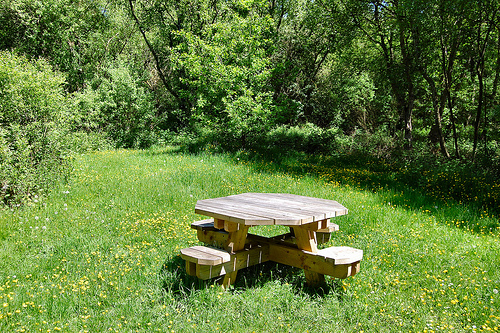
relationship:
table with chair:
[196, 191, 349, 246] [181, 244, 231, 262]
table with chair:
[196, 191, 349, 246] [303, 246, 365, 264]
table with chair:
[196, 191, 349, 246] [192, 219, 215, 230]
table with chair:
[196, 191, 349, 246] [320, 221, 337, 232]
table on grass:
[196, 191, 349, 246] [0, 142, 499, 333]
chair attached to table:
[303, 246, 365, 264] [196, 191, 349, 246]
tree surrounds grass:
[409, 0, 451, 158] [0, 142, 499, 333]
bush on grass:
[0, 46, 73, 217] [0, 142, 499, 333]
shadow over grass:
[160, 256, 222, 303] [0, 142, 499, 333]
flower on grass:
[424, 209, 429, 214] [0, 142, 499, 333]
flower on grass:
[387, 201, 393, 207] [0, 142, 499, 333]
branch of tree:
[378, 2, 399, 18] [379, 3, 426, 156]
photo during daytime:
[0, 0, 498, 333] [0, 2, 499, 332]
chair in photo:
[303, 246, 365, 264] [0, 0, 498, 333]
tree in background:
[379, 3, 426, 156] [2, 0, 499, 204]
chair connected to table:
[320, 221, 337, 232] [196, 191, 349, 246]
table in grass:
[196, 191, 349, 246] [0, 142, 499, 333]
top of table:
[197, 193, 350, 221] [196, 191, 349, 246]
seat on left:
[181, 244, 231, 262] [0, 1, 243, 332]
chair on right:
[320, 221, 337, 232] [241, 0, 499, 332]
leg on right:
[305, 272, 325, 293] [241, 0, 499, 332]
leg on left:
[222, 271, 239, 288] [0, 1, 243, 332]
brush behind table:
[224, 96, 272, 153] [196, 191, 349, 246]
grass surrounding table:
[0, 142, 499, 333] [196, 191, 349, 246]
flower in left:
[83, 275, 88, 281] [0, 1, 243, 332]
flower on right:
[424, 209, 429, 214] [241, 0, 499, 332]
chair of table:
[192, 219, 215, 230] [196, 191, 349, 246]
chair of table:
[181, 244, 231, 262] [196, 191, 349, 246]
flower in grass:
[424, 209, 429, 214] [0, 142, 499, 333]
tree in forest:
[409, 0, 451, 158] [0, 199, 497, 206]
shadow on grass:
[144, 139, 497, 236] [0, 142, 499, 333]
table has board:
[196, 191, 349, 246] [195, 203, 275, 224]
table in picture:
[196, 191, 349, 246] [0, 0, 498, 333]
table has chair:
[196, 191, 349, 246] [192, 219, 215, 230]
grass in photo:
[0, 142, 499, 333] [0, 0, 498, 333]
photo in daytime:
[0, 0, 498, 333] [0, 2, 499, 332]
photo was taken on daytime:
[0, 0, 498, 333] [0, 2, 499, 332]